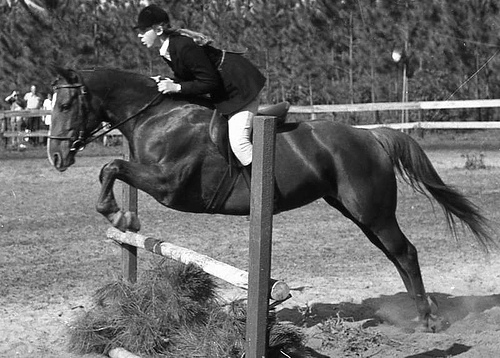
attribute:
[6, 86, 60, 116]
spectators — watching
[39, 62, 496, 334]
horse — jumping, black, racing, brown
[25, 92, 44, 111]
shirt — white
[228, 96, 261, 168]
pants — white, tight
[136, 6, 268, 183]
rider — riding, woman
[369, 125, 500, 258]
tail — black, long, hairy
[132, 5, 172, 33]
cap — black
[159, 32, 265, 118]
jacket — black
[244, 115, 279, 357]
post — long, black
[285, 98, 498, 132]
fence — large, white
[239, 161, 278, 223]
boots — black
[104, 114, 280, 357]
obstacle — equestrian